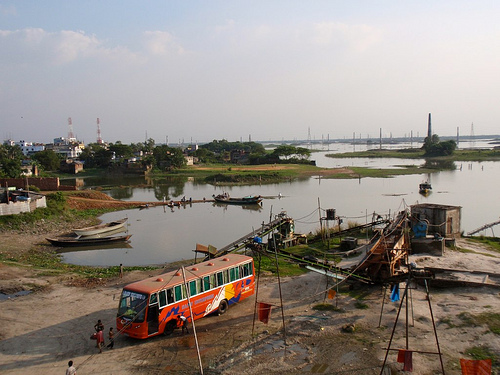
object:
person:
[174, 311, 192, 337]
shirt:
[177, 314, 188, 323]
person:
[102, 321, 121, 351]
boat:
[35, 210, 148, 254]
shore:
[0, 127, 500, 363]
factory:
[0, 113, 203, 174]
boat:
[207, 184, 283, 211]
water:
[33, 135, 499, 287]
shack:
[385, 187, 475, 245]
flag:
[384, 275, 405, 305]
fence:
[0, 183, 50, 219]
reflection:
[98, 170, 200, 207]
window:
[185, 279, 198, 297]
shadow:
[0, 279, 189, 367]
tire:
[160, 316, 184, 339]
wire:
[370, 256, 426, 316]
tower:
[87, 110, 105, 150]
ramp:
[62, 185, 195, 209]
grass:
[0, 242, 160, 280]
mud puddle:
[195, 304, 379, 374]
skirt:
[101, 327, 115, 351]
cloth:
[256, 301, 274, 328]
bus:
[113, 246, 261, 343]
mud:
[0, 232, 500, 374]